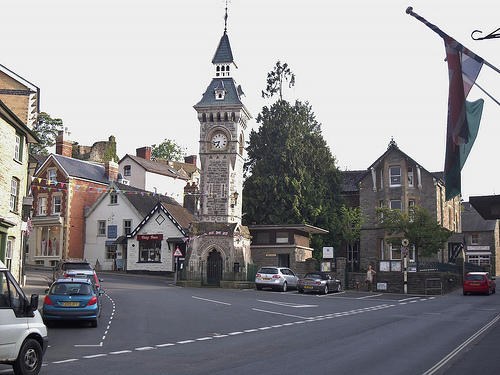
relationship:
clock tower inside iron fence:
[176, 0, 256, 290] [187, 261, 247, 286]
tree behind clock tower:
[245, 61, 354, 274] [176, 0, 256, 290]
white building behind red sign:
[79, 177, 189, 275] [135, 230, 164, 245]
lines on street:
[192, 314, 299, 337] [26, 232, 484, 369]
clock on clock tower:
[189, 79, 304, 186] [176, 0, 256, 290]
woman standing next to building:
[363, 260, 376, 290] [350, 143, 453, 285]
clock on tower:
[208, 129, 233, 151] [185, 22, 255, 281]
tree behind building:
[245, 61, 354, 274] [347, 133, 466, 296]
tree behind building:
[335, 205, 358, 278] [347, 133, 466, 296]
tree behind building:
[377, 205, 448, 270] [347, 133, 466, 296]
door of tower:
[200, 242, 224, 298] [173, 6, 254, 297]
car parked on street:
[255, 263, 297, 292] [26, 263, 498, 371]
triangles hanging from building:
[126, 191, 188, 252] [3, 99, 34, 288]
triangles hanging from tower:
[126, 191, 188, 252] [179, 27, 251, 290]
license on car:
[58, 297, 84, 308] [42, 271, 107, 332]